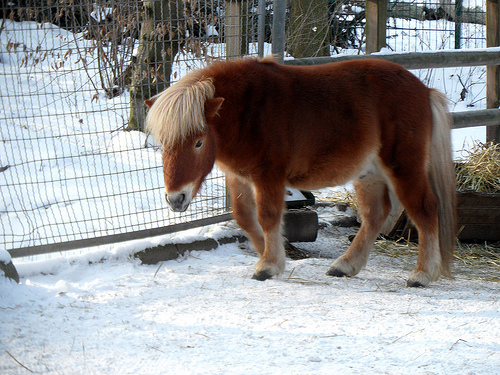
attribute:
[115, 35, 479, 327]
pony — brown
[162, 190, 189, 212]
nose — black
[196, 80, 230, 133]
ear — brown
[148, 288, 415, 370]
ground — snowy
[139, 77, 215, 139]
mane — blond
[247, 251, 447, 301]
horse — small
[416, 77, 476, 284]
tail — white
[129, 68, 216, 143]
hair — blond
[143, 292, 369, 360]
snow — white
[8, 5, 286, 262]
cage — white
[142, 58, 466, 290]
horse — beige, brown, small, dwarf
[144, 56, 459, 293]
miniature pony — brown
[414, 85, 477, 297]
tail — blond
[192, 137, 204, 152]
eye — black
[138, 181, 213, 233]
mouth — white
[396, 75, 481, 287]
tail — long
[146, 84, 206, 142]
head hair — white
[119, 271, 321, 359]
debris — hay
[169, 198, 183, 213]
nose — black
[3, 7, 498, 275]
fence — wire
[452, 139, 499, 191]
hay — is brown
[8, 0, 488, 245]
fence — metal, metallic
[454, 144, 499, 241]
trough — feed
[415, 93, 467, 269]
tail — blonde